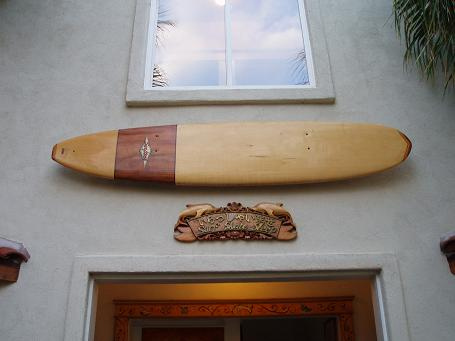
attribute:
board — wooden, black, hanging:
[31, 91, 426, 230]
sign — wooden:
[171, 209, 299, 263]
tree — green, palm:
[403, 16, 453, 56]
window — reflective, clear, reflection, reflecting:
[146, 5, 324, 99]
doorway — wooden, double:
[87, 249, 347, 326]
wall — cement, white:
[41, 34, 105, 105]